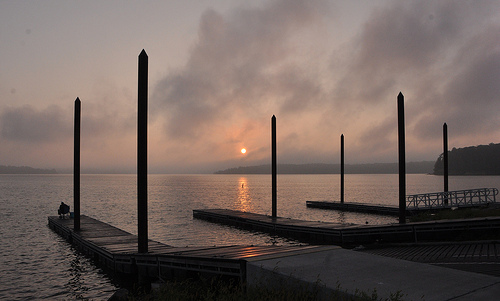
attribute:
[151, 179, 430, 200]
water — calm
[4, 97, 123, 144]
cloud — white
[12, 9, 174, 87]
sky — blue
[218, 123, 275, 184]
sun — pictured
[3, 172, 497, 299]
water — calm, large body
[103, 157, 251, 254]
water — calm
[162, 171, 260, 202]
water — body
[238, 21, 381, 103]
clouds — white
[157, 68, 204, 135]
clouds — white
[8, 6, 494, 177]
sky — blue, pictured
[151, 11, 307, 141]
clouds — grey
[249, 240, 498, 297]
walkway — concrete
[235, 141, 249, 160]
sun — pictured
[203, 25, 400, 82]
clouds — white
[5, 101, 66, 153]
clouds — white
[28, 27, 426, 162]
sky — blue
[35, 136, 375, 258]
water — calm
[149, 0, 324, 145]
cloud — pictured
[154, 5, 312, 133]
clouds — white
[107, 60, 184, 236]
pole — long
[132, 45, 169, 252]
pole — pictured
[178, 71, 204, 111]
clouds — white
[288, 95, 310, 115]
clouds — white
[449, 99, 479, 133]
clouds — white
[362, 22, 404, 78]
clouds — white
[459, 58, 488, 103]
clouds — white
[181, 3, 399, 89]
clouds — white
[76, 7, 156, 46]
sky — blue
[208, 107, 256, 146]
sky — blue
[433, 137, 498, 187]
hill — pictured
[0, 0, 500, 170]
clouds — white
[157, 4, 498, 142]
clouds — white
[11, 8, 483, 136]
sky — blue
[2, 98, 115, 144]
clouds — white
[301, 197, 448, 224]
dock — boat, wooden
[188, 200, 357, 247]
dock — boat, wooden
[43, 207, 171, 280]
dock — boat, wooden